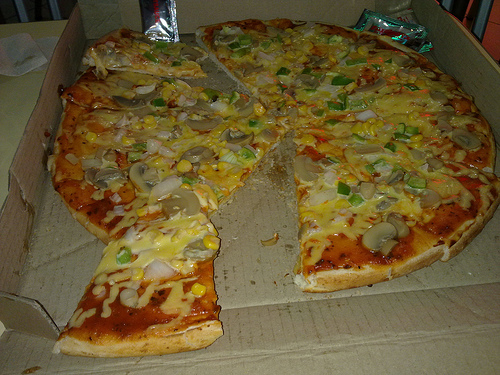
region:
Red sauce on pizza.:
[113, 315, 154, 333]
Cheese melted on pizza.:
[154, 279, 185, 297]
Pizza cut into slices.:
[150, 210, 240, 281]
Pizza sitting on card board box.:
[228, 208, 300, 293]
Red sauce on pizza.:
[336, 240, 350, 262]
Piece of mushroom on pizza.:
[367, 223, 401, 263]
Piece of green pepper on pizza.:
[345, 193, 365, 211]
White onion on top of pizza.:
[309, 188, 334, 204]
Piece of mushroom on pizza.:
[185, 145, 205, 159]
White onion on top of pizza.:
[155, 177, 185, 199]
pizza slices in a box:
[3, 14, 489, 357]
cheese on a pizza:
[78, 207, 227, 295]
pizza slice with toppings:
[73, 189, 237, 374]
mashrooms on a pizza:
[363, 201, 420, 278]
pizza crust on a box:
[50, 287, 276, 367]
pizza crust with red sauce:
[38, 304, 236, 361]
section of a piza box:
[10, 120, 100, 373]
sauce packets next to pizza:
[338, 4, 442, 59]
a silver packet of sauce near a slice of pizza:
[78, 4, 195, 81]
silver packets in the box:
[369, 13, 430, 50]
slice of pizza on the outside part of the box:
[91, 234, 214, 345]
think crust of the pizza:
[59, 330, 210, 359]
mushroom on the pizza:
[368, 219, 395, 255]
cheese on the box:
[256, 227, 286, 250]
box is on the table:
[16, 79, 64, 154]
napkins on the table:
[3, 18, 53, 79]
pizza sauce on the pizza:
[105, 316, 145, 329]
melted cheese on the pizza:
[313, 205, 333, 224]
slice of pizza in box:
[94, 220, 206, 364]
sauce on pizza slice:
[111, 312, 150, 330]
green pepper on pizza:
[113, 246, 136, 266]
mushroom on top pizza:
[361, 225, 397, 253]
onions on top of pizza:
[133, 80, 160, 95]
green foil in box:
[369, 16, 416, 38]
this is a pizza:
[64, 13, 486, 356]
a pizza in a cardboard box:
[30, 11, 498, 358]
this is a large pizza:
[44, 19, 499, 362]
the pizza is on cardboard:
[50, 20, 498, 343]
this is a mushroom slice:
[360, 221, 402, 258]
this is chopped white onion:
[135, 255, 182, 287]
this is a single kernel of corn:
[182, 275, 211, 300]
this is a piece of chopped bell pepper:
[105, 242, 132, 267]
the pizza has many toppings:
[52, 13, 497, 366]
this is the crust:
[56, 324, 238, 357]